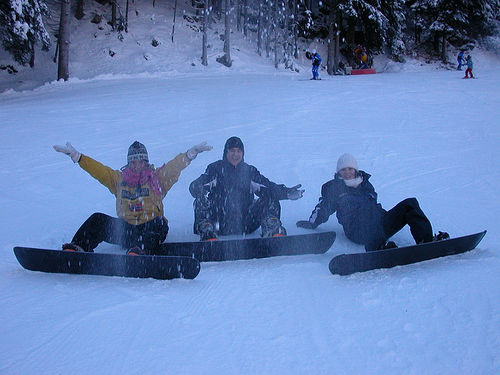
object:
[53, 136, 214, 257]
woman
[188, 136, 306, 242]
man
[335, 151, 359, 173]
cap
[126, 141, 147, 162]
cap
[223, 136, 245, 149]
cap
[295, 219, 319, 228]
gloves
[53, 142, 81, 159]
gloves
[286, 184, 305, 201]
gloves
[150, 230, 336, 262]
snowboard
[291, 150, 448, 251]
snowboarders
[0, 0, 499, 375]
snow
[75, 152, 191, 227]
sweatshirt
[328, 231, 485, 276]
snowboard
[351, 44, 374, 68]
person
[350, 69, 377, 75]
innertube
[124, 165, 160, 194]
scarf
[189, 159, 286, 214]
coat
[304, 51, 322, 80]
person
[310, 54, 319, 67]
uniform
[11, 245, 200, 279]
snowboard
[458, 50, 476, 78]
person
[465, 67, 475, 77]
pants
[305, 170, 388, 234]
suit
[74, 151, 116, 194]
arms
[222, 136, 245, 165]
head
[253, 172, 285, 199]
arm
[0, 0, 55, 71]
trees